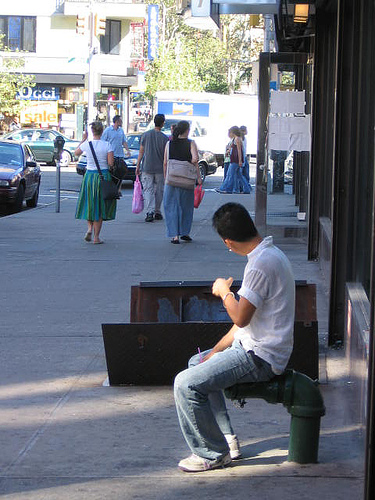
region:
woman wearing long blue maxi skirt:
[217, 123, 251, 196]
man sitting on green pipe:
[178, 202, 321, 473]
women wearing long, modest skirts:
[75, 117, 201, 246]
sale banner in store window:
[21, 102, 59, 122]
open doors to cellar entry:
[105, 277, 319, 385]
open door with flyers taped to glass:
[246, 59, 316, 245]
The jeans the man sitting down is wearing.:
[173, 346, 265, 461]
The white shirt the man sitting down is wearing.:
[231, 236, 295, 379]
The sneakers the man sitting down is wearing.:
[179, 431, 245, 476]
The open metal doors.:
[104, 277, 324, 377]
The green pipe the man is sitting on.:
[230, 370, 324, 463]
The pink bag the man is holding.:
[133, 174, 144, 213]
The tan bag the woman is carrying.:
[167, 160, 200, 184]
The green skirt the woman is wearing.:
[76, 166, 115, 223]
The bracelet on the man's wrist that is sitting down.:
[223, 289, 235, 301]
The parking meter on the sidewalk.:
[49, 134, 66, 210]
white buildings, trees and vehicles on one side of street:
[3, 3, 275, 162]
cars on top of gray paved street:
[2, 127, 291, 212]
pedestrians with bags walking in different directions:
[8, 109, 254, 246]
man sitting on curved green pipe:
[171, 200, 323, 473]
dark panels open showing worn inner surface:
[98, 268, 320, 388]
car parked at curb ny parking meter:
[3, 131, 64, 217]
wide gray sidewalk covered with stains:
[6, 180, 357, 493]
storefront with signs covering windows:
[2, 73, 126, 141]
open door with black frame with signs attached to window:
[255, 50, 315, 246]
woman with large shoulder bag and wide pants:
[163, 118, 204, 244]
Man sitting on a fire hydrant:
[173, 201, 326, 471]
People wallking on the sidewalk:
[75, 114, 250, 246]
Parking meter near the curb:
[51, 133, 65, 214]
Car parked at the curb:
[0, 140, 42, 210]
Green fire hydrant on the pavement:
[224, 368, 327, 468]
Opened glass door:
[255, 51, 313, 244]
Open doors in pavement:
[101, 276, 321, 387]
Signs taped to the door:
[267, 85, 312, 153]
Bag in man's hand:
[129, 174, 144, 215]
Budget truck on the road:
[150, 93, 262, 163]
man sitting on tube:
[157, 188, 313, 474]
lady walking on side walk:
[61, 112, 126, 250]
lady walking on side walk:
[150, 113, 217, 246]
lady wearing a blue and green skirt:
[68, 118, 124, 247]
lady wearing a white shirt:
[75, 116, 122, 173]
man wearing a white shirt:
[203, 221, 314, 376]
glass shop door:
[233, 43, 336, 254]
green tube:
[214, 349, 338, 489]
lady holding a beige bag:
[156, 134, 214, 218]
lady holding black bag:
[78, 135, 134, 201]